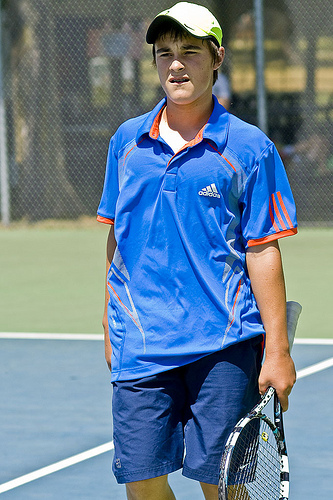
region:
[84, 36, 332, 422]
boy in blue playing tennis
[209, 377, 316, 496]
white striped tennis racket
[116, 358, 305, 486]
blue shorts on boy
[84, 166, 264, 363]
blue and orange shirt on boy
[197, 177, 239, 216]
adidas logo on shirt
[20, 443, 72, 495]
white lines on tennis court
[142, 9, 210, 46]
green hat on boy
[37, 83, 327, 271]
chain link fence in background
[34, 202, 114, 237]
brown leaves by fence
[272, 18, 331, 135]
trees behind metal fence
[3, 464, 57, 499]
White line on pavement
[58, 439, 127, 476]
White line on pavement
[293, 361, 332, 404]
White line on pavement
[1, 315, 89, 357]
White line on pavement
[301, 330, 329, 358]
White line on pavement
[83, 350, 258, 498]
Person wearing blue shorts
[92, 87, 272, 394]
PErson wearing blue and white shirt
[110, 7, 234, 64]
Green and white hat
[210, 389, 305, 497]
White and blue tennis racket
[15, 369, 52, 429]
Blue color painted pavement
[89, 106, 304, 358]
blue and orange shirt of tennis player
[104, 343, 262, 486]
blue shorts with white nike swoosh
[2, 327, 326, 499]
white lines of tennis court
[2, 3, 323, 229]
fencing behind tennis court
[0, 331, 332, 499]
blue tennis court with white lines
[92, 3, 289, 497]
young man holding tennis racket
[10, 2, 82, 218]
tree trunk behind fencing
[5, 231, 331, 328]
green surface surrounding tennis court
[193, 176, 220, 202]
white adidas logo on blue shirt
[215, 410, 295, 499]
white stripes on tennis racket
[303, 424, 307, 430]
part of a court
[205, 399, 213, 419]
part of a short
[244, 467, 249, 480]
part of a racket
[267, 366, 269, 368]
part of a finger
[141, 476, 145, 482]
part of a knee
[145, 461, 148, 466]
part of a short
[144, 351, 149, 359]
part of a shirt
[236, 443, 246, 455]
edge of a racket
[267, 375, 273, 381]
part of a thumb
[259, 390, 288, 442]
part of a racket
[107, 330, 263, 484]
Boy is wearing shorts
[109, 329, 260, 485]
Boy is wearing blue shorts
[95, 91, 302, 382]
Boy is wearing a shirt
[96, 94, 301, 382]
Boy is wearing a blue and red shirt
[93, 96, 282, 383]
Boy is wearing a short sleeved shirt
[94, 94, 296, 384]
Boy is wearing a blue and red short sleeved shirt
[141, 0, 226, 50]
Boy is wearing a hat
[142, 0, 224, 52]
Boy is wearing a green and white hat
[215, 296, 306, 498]
Boy is holding a racket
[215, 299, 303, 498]
Boy is holding a tennis racket